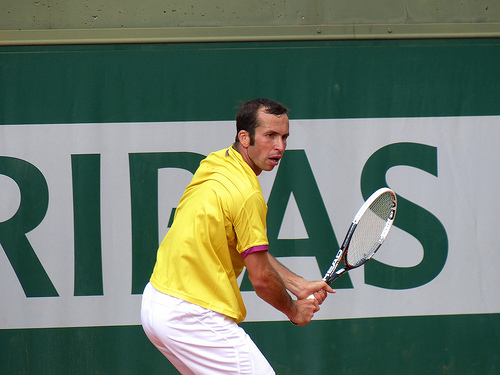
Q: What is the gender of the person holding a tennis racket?
A: Male.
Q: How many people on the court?
A: One.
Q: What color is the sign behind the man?
A: Green and white.